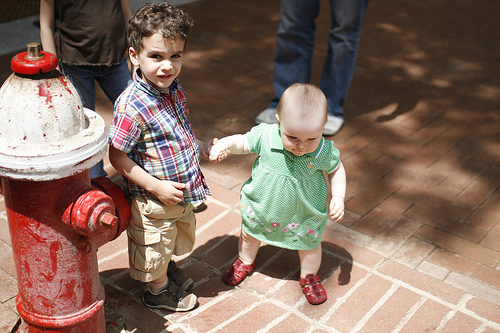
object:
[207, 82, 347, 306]
baby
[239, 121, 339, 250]
dress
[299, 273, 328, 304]
sandal's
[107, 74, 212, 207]
shirt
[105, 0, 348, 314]
two children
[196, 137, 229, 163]
hands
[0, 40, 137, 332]
fire hydrant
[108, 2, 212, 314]
boy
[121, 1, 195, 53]
hair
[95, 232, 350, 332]
shadows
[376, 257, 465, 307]
bricks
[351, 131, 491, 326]
ground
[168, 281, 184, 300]
straps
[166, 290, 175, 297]
velcro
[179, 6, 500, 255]
shade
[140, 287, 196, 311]
shoes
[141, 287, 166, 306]
ankle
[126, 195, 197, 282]
pants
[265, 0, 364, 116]
pants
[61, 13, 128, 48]
belly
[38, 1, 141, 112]
woman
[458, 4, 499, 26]
tree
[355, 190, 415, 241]
slabs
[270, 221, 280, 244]
flowers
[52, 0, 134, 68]
shirt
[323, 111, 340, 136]
shoes